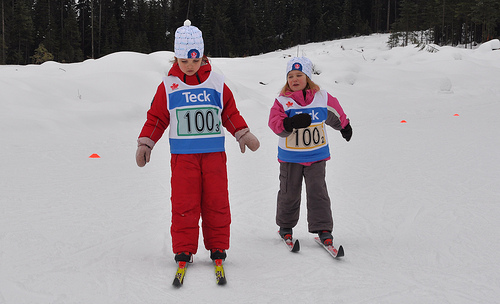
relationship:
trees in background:
[1, 1, 499, 66] [22, 0, 338, 58]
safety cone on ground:
[89, 153, 101, 159] [1, 29, 499, 304]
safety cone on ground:
[399, 119, 407, 124] [1, 29, 499, 304]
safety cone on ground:
[453, 112, 460, 117] [1, 29, 499, 304]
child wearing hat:
[134, 19, 261, 262] [173, 19, 204, 60]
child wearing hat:
[267, 56, 353, 246] [286, 55, 315, 81]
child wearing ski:
[134, 19, 261, 262] [172, 261, 186, 286]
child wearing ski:
[134, 19, 261, 262] [213, 259, 226, 285]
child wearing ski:
[267, 56, 353, 246] [277, 230, 301, 254]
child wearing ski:
[267, 56, 353, 246] [312, 236, 345, 260]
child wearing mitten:
[267, 56, 353, 246] [282, 113, 311, 132]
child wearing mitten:
[267, 56, 353, 246] [340, 124, 353, 141]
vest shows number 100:
[162, 70, 226, 155] [184, 109, 216, 133]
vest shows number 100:
[275, 89, 330, 163] [292, 127, 320, 149]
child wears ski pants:
[267, 56, 353, 246] [276, 160, 333, 234]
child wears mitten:
[134, 19, 261, 262] [136, 144, 152, 167]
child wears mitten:
[134, 19, 261, 262] [238, 131, 260, 154]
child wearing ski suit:
[134, 19, 261, 262] [137, 55, 249, 254]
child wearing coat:
[267, 56, 353, 246] [269, 86, 349, 167]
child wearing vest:
[134, 19, 261, 262] [162, 70, 226, 155]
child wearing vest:
[267, 56, 353, 246] [275, 89, 330, 163]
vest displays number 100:
[162, 70, 226, 155] [184, 109, 216, 133]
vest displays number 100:
[275, 89, 330, 163] [292, 127, 320, 149]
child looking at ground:
[134, 19, 261, 262] [1, 29, 499, 304]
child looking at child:
[267, 56, 353, 246] [134, 19, 261, 262]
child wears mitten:
[267, 56, 353, 246] [282, 113, 311, 132]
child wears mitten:
[267, 56, 353, 246] [340, 124, 353, 141]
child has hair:
[267, 56, 353, 246] [277, 74, 320, 97]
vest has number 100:
[275, 89, 330, 163] [292, 127, 320, 149]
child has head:
[267, 56, 353, 246] [287, 58, 313, 88]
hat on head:
[286, 55, 315, 81] [287, 58, 313, 88]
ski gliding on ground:
[172, 261, 186, 286] [1, 29, 499, 304]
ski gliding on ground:
[213, 259, 226, 285] [1, 29, 499, 304]